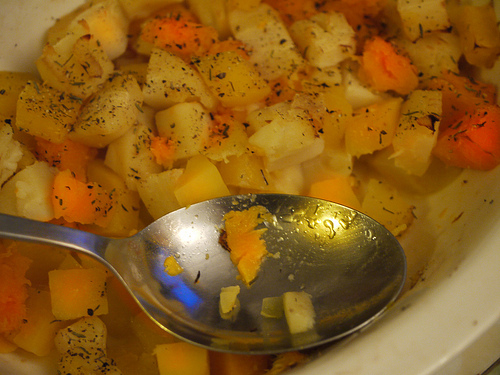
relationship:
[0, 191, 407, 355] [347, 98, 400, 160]
spoon with potatoe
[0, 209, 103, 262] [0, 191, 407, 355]
handle of spoon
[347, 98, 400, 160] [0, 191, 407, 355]
potatoe on spoon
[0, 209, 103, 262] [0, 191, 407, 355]
handle on spoon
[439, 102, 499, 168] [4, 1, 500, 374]
carrot in bowl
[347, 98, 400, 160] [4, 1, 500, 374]
potatoe in bowl